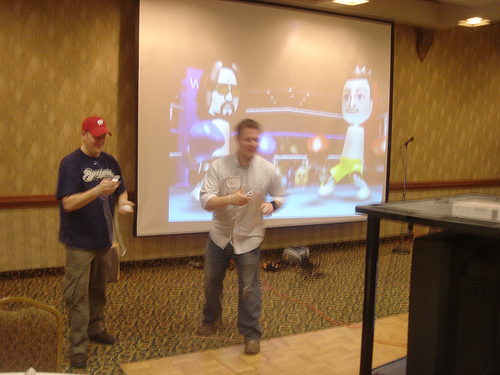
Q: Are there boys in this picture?
A: No, there are no boys.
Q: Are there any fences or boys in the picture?
A: No, there are no boys or fences.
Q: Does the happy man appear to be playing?
A: Yes, the man is playing.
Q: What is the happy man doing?
A: The man is playing.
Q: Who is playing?
A: The man is playing.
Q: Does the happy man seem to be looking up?
A: No, the man is playing.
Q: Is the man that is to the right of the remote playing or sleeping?
A: The man is playing.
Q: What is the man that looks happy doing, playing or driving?
A: The man is playing.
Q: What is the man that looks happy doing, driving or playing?
A: The man is playing.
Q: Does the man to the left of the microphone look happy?
A: Yes, the man is happy.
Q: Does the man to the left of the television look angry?
A: No, the man is happy.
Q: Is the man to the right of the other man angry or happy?
A: The man is happy.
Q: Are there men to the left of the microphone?
A: Yes, there is a man to the left of the microphone.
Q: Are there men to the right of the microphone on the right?
A: No, the man is to the left of the microphone.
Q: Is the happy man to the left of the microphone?
A: Yes, the man is to the left of the microphone.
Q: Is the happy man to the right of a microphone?
A: No, the man is to the left of a microphone.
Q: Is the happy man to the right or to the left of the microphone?
A: The man is to the left of the microphone.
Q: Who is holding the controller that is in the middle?
A: The man is holding the controller.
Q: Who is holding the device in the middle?
A: The man is holding the controller.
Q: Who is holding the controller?
A: The man is holding the controller.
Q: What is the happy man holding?
A: The man is holding the controller.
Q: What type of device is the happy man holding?
A: The man is holding the controller.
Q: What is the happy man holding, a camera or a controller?
A: The man is holding a controller.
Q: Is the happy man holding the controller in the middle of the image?
A: Yes, the man is holding the controller.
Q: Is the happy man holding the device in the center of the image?
A: Yes, the man is holding the controller.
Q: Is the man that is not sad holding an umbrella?
A: No, the man is holding the controller.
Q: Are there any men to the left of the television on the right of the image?
A: Yes, there is a man to the left of the television.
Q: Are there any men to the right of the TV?
A: No, the man is to the left of the TV.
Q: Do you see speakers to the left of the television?
A: No, there is a man to the left of the television.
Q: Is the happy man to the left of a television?
A: Yes, the man is to the left of a television.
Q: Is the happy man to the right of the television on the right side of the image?
A: No, the man is to the left of the TV.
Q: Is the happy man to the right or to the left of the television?
A: The man is to the left of the television.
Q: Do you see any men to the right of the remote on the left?
A: Yes, there is a man to the right of the remote.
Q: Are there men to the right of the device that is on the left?
A: Yes, there is a man to the right of the remote.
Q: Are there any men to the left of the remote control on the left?
A: No, the man is to the right of the remote control.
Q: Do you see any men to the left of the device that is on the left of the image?
A: No, the man is to the right of the remote control.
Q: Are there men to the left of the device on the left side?
A: No, the man is to the right of the remote control.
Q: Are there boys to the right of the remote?
A: No, there is a man to the right of the remote.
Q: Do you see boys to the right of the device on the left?
A: No, there is a man to the right of the remote.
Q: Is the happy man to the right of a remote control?
A: Yes, the man is to the right of a remote control.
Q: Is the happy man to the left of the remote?
A: No, the man is to the right of the remote.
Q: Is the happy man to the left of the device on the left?
A: No, the man is to the right of the remote.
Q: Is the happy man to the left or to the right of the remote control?
A: The man is to the right of the remote control.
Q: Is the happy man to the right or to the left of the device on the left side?
A: The man is to the right of the remote control.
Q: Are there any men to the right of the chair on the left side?
A: Yes, there is a man to the right of the chair.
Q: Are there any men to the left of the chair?
A: No, the man is to the right of the chair.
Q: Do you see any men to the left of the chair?
A: No, the man is to the right of the chair.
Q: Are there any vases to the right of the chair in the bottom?
A: No, there is a man to the right of the chair.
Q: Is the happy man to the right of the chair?
A: Yes, the man is to the right of the chair.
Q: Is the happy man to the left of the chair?
A: No, the man is to the right of the chair.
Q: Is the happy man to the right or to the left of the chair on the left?
A: The man is to the right of the chair.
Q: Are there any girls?
A: No, there are no girls.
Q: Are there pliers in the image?
A: No, there are no pliers.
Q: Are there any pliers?
A: No, there are no pliers.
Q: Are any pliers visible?
A: No, there are no pliers.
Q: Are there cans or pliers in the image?
A: No, there are no pliers or cans.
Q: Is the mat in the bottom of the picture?
A: Yes, the mat is in the bottom of the image.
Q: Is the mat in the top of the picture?
A: No, the mat is in the bottom of the image.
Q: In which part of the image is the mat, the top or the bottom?
A: The mat is in the bottom of the image.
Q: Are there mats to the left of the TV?
A: Yes, there is a mat to the left of the TV.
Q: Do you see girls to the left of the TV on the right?
A: No, there is a mat to the left of the TV.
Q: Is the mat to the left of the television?
A: Yes, the mat is to the left of the television.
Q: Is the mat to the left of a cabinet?
A: No, the mat is to the left of the television.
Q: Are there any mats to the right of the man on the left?
A: Yes, there is a mat to the right of the man.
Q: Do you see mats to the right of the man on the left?
A: Yes, there is a mat to the right of the man.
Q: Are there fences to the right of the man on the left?
A: No, there is a mat to the right of the man.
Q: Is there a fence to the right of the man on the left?
A: No, there is a mat to the right of the man.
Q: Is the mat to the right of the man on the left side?
A: Yes, the mat is to the right of the man.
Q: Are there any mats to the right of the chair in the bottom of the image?
A: Yes, there is a mat to the right of the chair.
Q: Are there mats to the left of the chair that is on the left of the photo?
A: No, the mat is to the right of the chair.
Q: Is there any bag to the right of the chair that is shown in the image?
A: No, there is a mat to the right of the chair.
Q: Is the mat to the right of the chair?
A: Yes, the mat is to the right of the chair.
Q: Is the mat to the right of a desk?
A: No, the mat is to the right of the chair.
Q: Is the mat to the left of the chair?
A: No, the mat is to the right of the chair.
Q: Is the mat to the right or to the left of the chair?
A: The mat is to the right of the chair.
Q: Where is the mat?
A: The mat is on the floor.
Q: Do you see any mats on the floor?
A: Yes, there is a mat on the floor.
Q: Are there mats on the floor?
A: Yes, there is a mat on the floor.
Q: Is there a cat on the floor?
A: No, there is a mat on the floor.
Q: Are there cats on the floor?
A: No, there is a mat on the floor.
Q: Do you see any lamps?
A: No, there are no lamps.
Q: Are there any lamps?
A: No, there are no lamps.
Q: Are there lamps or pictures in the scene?
A: No, there are no lamps or pictures.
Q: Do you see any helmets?
A: No, there are no helmets.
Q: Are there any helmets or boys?
A: No, there are no helmets or boys.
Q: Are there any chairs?
A: Yes, there is a chair.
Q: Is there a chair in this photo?
A: Yes, there is a chair.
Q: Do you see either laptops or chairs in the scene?
A: Yes, there is a chair.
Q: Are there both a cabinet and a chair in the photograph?
A: No, there is a chair but no cabinets.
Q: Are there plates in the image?
A: No, there are no plates.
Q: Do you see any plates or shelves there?
A: No, there are no plates or shelves.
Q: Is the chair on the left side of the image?
A: Yes, the chair is on the left of the image.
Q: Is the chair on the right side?
A: No, the chair is on the left of the image.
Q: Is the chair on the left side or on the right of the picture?
A: The chair is on the left of the image.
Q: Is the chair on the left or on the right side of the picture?
A: The chair is on the left of the image.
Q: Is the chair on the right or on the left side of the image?
A: The chair is on the left of the image.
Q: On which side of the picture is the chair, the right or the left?
A: The chair is on the left of the image.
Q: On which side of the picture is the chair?
A: The chair is on the left of the image.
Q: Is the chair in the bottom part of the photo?
A: Yes, the chair is in the bottom of the image.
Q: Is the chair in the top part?
A: No, the chair is in the bottom of the image.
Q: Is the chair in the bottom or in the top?
A: The chair is in the bottom of the image.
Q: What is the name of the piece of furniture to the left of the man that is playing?
A: The piece of furniture is a chair.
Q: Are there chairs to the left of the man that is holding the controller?
A: Yes, there is a chair to the left of the man.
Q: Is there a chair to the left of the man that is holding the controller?
A: Yes, there is a chair to the left of the man.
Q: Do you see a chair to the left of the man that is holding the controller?
A: Yes, there is a chair to the left of the man.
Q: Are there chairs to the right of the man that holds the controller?
A: No, the chair is to the left of the man.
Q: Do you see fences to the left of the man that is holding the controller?
A: No, there is a chair to the left of the man.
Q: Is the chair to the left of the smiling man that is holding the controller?
A: Yes, the chair is to the left of the man.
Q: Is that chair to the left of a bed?
A: No, the chair is to the left of the man.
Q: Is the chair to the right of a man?
A: No, the chair is to the left of a man.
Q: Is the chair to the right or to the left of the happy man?
A: The chair is to the left of the man.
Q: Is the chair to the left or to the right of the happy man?
A: The chair is to the left of the man.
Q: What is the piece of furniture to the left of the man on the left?
A: The piece of furniture is a chair.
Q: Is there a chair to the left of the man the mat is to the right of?
A: Yes, there is a chair to the left of the man.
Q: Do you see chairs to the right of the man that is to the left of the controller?
A: No, the chair is to the left of the man.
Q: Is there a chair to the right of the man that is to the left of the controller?
A: No, the chair is to the left of the man.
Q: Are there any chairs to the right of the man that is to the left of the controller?
A: No, the chair is to the left of the man.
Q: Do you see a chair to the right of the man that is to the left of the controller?
A: No, the chair is to the left of the man.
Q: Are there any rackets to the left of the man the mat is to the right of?
A: No, there is a chair to the left of the man.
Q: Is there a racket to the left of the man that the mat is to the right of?
A: No, there is a chair to the left of the man.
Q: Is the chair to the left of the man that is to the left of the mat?
A: Yes, the chair is to the left of the man.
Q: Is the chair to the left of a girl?
A: No, the chair is to the left of the man.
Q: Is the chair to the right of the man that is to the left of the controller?
A: No, the chair is to the left of the man.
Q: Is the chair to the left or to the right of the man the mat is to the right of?
A: The chair is to the left of the man.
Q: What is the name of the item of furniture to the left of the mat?
A: The piece of furniture is a chair.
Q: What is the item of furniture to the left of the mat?
A: The piece of furniture is a chair.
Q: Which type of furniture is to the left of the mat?
A: The piece of furniture is a chair.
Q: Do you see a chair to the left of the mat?
A: Yes, there is a chair to the left of the mat.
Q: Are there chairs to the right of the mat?
A: No, the chair is to the left of the mat.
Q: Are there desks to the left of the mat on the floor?
A: No, there is a chair to the left of the mat.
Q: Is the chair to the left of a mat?
A: Yes, the chair is to the left of a mat.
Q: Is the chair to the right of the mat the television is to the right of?
A: No, the chair is to the left of the mat.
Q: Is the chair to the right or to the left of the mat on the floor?
A: The chair is to the left of the mat.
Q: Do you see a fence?
A: No, there are no fences.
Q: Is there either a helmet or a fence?
A: No, there are no fences or helmets.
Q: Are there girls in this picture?
A: No, there are no girls.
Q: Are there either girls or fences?
A: No, there are no girls or fences.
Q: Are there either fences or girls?
A: No, there are no girls or fences.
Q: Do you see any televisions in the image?
A: Yes, there is a television.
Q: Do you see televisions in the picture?
A: Yes, there is a television.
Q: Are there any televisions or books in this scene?
A: Yes, there is a television.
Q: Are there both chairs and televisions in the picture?
A: Yes, there are both a television and a chair.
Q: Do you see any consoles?
A: No, there are no consoles.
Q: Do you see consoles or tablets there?
A: No, there are no consoles or tablets.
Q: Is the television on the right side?
A: Yes, the television is on the right of the image.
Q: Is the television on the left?
A: No, the television is on the right of the image.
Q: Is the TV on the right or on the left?
A: The TV is on the right of the image.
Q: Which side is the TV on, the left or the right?
A: The TV is on the right of the image.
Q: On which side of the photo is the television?
A: The television is on the right of the image.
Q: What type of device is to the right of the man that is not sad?
A: The device is a television.